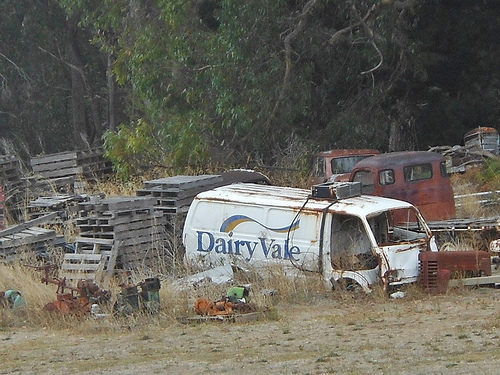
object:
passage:
[0, 289, 499, 374]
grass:
[0, 258, 57, 326]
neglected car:
[178, 177, 440, 295]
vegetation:
[63, 0, 498, 184]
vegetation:
[1, 0, 136, 175]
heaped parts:
[0, 148, 170, 288]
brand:
[195, 228, 299, 264]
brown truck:
[348, 149, 498, 259]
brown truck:
[307, 143, 383, 193]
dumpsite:
[0, 124, 499, 327]